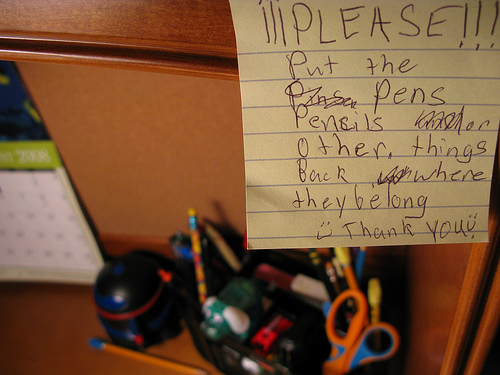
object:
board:
[18, 63, 247, 256]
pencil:
[89, 338, 207, 375]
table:
[11, 304, 80, 367]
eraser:
[368, 278, 383, 305]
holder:
[321, 288, 398, 375]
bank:
[92, 249, 183, 353]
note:
[222, 0, 500, 251]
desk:
[0, 278, 208, 374]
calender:
[0, 0, 500, 375]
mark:
[259, 0, 287, 46]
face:
[315, 211, 339, 245]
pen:
[307, 246, 383, 351]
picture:
[0, 60, 53, 142]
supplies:
[87, 206, 400, 375]